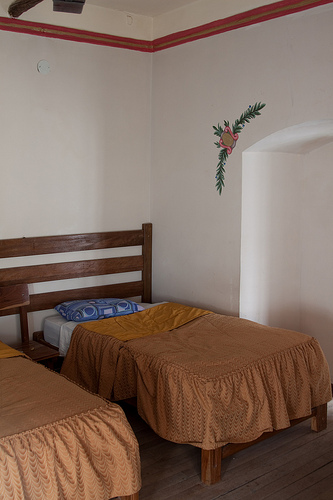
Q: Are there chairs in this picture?
A: Yes, there is a chair.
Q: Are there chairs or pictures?
A: Yes, there is a chair.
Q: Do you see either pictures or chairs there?
A: Yes, there is a chair.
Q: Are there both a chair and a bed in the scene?
A: Yes, there are both a chair and a bed.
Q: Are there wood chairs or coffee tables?
A: Yes, there is a wood chair.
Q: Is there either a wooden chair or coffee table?
A: Yes, there is a wood chair.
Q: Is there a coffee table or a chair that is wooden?
A: Yes, the chair is wooden.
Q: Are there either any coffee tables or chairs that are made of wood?
A: Yes, the chair is made of wood.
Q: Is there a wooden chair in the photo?
A: Yes, there is a wood chair.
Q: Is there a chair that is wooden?
A: Yes, there is a chair that is wooden.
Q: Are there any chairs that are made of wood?
A: Yes, there is a chair that is made of wood.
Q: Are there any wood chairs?
A: Yes, there is a chair that is made of wood.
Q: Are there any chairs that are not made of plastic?
A: Yes, there is a chair that is made of wood.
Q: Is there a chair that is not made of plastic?
A: Yes, there is a chair that is made of wood.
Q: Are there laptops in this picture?
A: No, there are no laptops.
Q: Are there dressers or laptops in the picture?
A: No, there are no laptops or dressers.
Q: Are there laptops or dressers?
A: No, there are no laptops or dressers.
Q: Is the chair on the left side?
A: Yes, the chair is on the left of the image.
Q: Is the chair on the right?
A: No, the chair is on the left of the image.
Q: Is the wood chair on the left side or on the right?
A: The chair is on the left of the image.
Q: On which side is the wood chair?
A: The chair is on the left of the image.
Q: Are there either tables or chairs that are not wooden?
A: No, there is a chair but it is wooden.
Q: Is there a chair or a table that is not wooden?
A: No, there is a chair but it is wooden.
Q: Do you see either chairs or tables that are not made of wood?
A: No, there is a chair but it is made of wood.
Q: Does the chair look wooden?
A: Yes, the chair is wooden.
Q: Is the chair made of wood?
A: Yes, the chair is made of wood.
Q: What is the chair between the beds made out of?
A: The chair is made of wood.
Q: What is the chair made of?
A: The chair is made of wood.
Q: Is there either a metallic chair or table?
A: No, there is a chair but it is wooden.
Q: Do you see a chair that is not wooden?
A: No, there is a chair but it is wooden.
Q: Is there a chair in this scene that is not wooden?
A: No, there is a chair but it is wooden.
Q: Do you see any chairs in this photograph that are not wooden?
A: No, there is a chair but it is wooden.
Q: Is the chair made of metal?
A: No, the chair is made of wood.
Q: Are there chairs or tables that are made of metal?
A: No, there is a chair but it is made of wood.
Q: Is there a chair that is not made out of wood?
A: No, there is a chair but it is made of wood.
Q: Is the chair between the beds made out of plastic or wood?
A: The chair is made of wood.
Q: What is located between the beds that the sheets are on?
A: The chair is between the beds.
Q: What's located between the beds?
A: The chair is between the beds.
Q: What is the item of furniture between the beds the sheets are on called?
A: The piece of furniture is a chair.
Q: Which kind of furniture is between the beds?
A: The piece of furniture is a chair.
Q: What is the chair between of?
A: The chair is between the beds.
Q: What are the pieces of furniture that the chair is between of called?
A: The pieces of furniture are beds.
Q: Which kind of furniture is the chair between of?
A: The chair is between the beds.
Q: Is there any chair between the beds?
A: Yes, there is a chair between the beds.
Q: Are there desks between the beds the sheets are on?
A: No, there is a chair between the beds.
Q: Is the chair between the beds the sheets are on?
A: Yes, the chair is between the beds.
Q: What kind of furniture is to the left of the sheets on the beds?
A: The piece of furniture is a chair.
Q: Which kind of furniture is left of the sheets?
A: The piece of furniture is a chair.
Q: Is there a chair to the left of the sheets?
A: Yes, there is a chair to the left of the sheets.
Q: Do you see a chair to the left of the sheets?
A: Yes, there is a chair to the left of the sheets.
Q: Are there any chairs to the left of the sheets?
A: Yes, there is a chair to the left of the sheets.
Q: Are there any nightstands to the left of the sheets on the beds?
A: No, there is a chair to the left of the sheets.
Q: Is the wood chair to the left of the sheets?
A: Yes, the chair is to the left of the sheets.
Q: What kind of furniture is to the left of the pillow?
A: The piece of furniture is a chair.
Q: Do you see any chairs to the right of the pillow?
A: No, the chair is to the left of the pillow.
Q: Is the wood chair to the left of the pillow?
A: Yes, the chair is to the left of the pillow.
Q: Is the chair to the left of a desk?
A: No, the chair is to the left of the pillow.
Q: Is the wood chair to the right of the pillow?
A: No, the chair is to the left of the pillow.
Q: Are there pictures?
A: No, there are no pictures.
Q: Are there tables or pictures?
A: No, there are no pictures or tables.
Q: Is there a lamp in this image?
A: No, there are no lamps.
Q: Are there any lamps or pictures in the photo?
A: No, there are no lamps or pictures.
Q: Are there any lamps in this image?
A: No, there are no lamps.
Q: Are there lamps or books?
A: No, there are no lamps or books.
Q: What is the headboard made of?
A: The head board is made of wood.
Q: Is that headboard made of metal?
A: No, the headboard is made of wood.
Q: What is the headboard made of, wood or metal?
A: The headboard is made of wood.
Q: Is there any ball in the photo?
A: No, there are no balls.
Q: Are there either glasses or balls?
A: No, there are no balls or glasses.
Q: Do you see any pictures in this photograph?
A: No, there are no pictures.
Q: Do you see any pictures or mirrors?
A: No, there are no pictures or mirrors.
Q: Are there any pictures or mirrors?
A: No, there are no pictures or mirrors.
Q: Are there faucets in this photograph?
A: No, there are no faucets.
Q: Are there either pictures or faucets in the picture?
A: No, there are no faucets or pictures.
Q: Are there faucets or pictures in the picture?
A: No, there are no faucets or pictures.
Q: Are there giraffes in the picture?
A: No, there are no giraffes.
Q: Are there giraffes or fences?
A: No, there are no giraffes or fences.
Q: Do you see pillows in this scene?
A: Yes, there is a pillow.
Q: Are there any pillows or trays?
A: Yes, there is a pillow.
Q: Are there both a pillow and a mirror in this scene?
A: No, there is a pillow but no mirrors.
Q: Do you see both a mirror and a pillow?
A: No, there is a pillow but no mirrors.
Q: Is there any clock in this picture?
A: No, there are no clocks.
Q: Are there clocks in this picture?
A: No, there are no clocks.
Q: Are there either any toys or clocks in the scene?
A: No, there are no clocks or toys.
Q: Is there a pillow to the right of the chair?
A: Yes, there is a pillow to the right of the chair.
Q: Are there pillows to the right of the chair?
A: Yes, there is a pillow to the right of the chair.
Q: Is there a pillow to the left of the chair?
A: No, the pillow is to the right of the chair.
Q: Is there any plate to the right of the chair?
A: No, there is a pillow to the right of the chair.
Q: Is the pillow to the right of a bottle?
A: No, the pillow is to the right of the chair.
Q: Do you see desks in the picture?
A: No, there are no desks.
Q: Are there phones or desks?
A: No, there are no desks or phones.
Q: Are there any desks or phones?
A: No, there are no desks or phones.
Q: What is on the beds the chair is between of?
A: The sheets are on the beds.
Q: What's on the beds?
A: The sheets are on the beds.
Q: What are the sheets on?
A: The sheets are on the beds.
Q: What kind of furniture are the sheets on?
A: The sheets are on the beds.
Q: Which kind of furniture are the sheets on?
A: The sheets are on the beds.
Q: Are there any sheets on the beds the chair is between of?
A: Yes, there are sheets on the beds.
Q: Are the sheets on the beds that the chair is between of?
A: Yes, the sheets are on the beds.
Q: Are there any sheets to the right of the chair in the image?
A: Yes, there are sheets to the right of the chair.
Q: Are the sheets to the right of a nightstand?
A: No, the sheets are to the right of a chair.